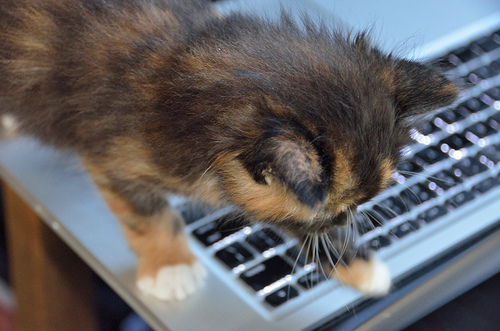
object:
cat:
[0, 0, 460, 303]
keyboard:
[0, 0, 499, 331]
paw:
[137, 247, 208, 301]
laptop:
[2, 0, 499, 331]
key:
[215, 240, 255, 270]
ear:
[389, 56, 460, 122]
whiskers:
[282, 231, 360, 319]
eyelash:
[285, 169, 465, 321]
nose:
[334, 210, 358, 226]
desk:
[0, 0, 500, 331]